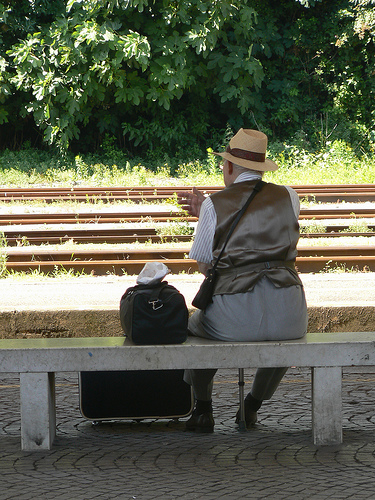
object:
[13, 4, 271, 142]
tree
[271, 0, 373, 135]
tree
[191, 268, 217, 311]
bag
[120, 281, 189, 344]
bag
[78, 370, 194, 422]
bag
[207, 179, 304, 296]
vest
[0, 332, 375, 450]
bench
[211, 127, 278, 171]
hat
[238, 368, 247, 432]
cane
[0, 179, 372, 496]
ground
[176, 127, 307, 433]
man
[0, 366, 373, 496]
walkway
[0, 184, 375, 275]
track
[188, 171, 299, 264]
dress shirt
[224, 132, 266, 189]
person's head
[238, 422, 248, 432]
tip